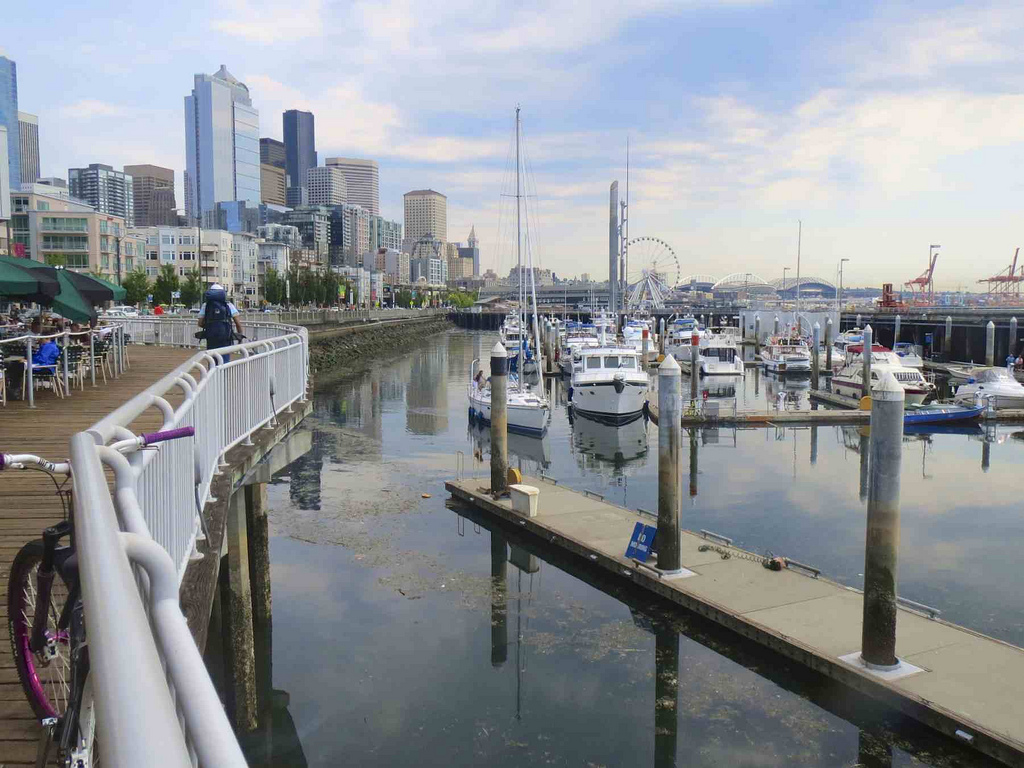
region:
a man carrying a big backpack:
[189, 278, 250, 371]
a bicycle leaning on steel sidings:
[10, 407, 219, 766]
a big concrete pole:
[822, 361, 925, 685]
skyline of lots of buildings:
[183, 62, 494, 329]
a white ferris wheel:
[616, 228, 678, 323]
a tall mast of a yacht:
[465, 91, 563, 439]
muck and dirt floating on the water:
[293, 481, 424, 574]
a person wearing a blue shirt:
[21, 323, 75, 393]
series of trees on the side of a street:
[253, 258, 364, 328]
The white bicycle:
[4, 431, 191, 764]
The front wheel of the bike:
[5, 548, 89, 720]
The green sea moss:
[276, 404, 792, 762]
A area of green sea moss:
[295, 414, 842, 760]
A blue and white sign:
[612, 516, 658, 568]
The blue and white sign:
[615, 513, 661, 570]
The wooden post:
[479, 329, 512, 497]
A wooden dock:
[451, 462, 1021, 761]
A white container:
[501, 478, 562, 540]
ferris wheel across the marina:
[618, 228, 685, 299]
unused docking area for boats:
[448, 326, 1022, 766]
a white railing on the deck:
[65, 316, 318, 766]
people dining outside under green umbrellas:
[8, 246, 130, 402]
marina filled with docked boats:
[427, 276, 1020, 429]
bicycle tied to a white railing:
[5, 431, 214, 764]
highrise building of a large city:
[0, 50, 485, 301]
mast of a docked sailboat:
[505, 98, 540, 409]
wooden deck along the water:
[3, 328, 235, 766]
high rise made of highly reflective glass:
[180, 63, 261, 232]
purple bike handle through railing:
[111, 423, 198, 458]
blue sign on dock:
[623, 518, 662, 560]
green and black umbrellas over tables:
[3, 241, 127, 321]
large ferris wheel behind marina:
[610, 231, 680, 309]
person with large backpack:
[192, 284, 247, 367]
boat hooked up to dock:
[566, 334, 650, 427]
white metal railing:
[66, 319, 310, 763]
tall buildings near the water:
[0, 51, 479, 286]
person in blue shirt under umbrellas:
[29, 329, 58, 372]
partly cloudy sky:
[2, 2, 1023, 288]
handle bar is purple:
[125, 425, 223, 458]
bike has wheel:
[12, 533, 86, 729]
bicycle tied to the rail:
[24, 425, 126, 765]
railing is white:
[59, 432, 266, 765]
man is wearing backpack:
[195, 292, 234, 349]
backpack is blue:
[204, 279, 244, 377]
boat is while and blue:
[558, 333, 658, 438]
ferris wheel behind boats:
[610, 235, 681, 322]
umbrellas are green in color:
[11, 253, 88, 317]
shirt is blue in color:
[34, 337, 64, 379]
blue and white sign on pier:
[612, 514, 666, 572]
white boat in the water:
[563, 328, 656, 442]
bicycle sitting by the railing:
[0, 420, 143, 765]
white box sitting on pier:
[502, 477, 547, 529]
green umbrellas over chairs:
[8, 250, 130, 326]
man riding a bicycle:
[174, 274, 247, 370]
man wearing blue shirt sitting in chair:
[25, 323, 70, 393]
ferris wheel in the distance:
[604, 220, 688, 304]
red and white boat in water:
[817, 334, 934, 414]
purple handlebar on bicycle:
[128, 418, 208, 456]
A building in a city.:
[302, 165, 348, 204]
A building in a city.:
[170, 58, 266, 202]